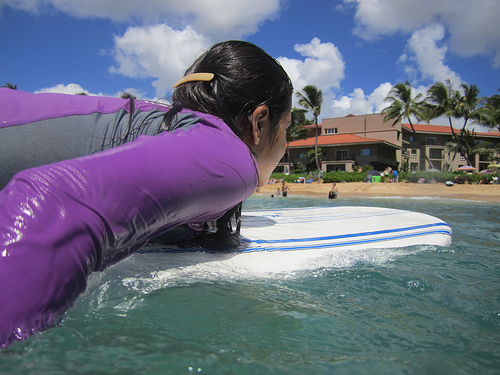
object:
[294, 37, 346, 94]
cloud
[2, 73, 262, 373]
wetsuit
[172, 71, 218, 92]
wooden barrett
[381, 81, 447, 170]
tree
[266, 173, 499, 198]
ground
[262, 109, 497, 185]
building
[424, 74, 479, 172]
trees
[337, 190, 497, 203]
shoreline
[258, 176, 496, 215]
shore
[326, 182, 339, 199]
people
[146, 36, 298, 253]
hair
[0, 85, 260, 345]
wetsuit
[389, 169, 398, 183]
people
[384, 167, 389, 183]
people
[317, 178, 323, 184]
people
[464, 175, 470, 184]
people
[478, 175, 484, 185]
people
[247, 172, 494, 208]
shore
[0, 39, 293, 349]
woman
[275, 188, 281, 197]
child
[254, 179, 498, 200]
sand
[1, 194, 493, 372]
water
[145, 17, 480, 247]
headed towards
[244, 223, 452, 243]
blue stripe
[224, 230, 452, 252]
blue stripe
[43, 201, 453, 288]
surfboard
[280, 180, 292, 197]
people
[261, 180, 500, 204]
beach